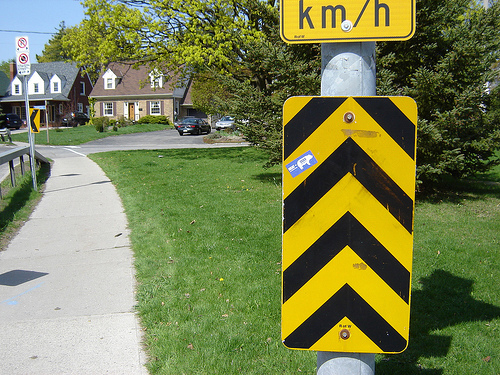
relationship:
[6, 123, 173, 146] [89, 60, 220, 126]
lawn in front of house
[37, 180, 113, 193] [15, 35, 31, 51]
shadow cast by sign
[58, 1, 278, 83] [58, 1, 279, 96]
flowers growing on tree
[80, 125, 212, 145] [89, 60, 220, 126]
driveway next to house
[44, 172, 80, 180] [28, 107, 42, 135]
shadow cast by sign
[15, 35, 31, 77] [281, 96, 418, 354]
sign to left of sign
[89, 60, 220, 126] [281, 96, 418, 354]
house behind sign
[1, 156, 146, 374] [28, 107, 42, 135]
sidewalk behind sign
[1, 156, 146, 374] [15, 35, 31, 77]
sidewalk behind sign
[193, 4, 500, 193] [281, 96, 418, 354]
evergreen behind sign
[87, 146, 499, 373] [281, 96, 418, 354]
grass behind sign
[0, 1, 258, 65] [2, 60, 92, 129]
sky above house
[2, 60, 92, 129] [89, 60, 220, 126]
house to left of house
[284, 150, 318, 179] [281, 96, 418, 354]
sticker attached to sign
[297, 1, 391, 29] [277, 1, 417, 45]
text printed on sign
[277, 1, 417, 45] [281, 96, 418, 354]
sign above sign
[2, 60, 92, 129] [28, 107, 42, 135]
house behind sign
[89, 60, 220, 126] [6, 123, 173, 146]
house behind lawn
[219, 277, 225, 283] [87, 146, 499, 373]
dandelion growing in grass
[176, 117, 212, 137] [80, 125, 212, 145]
car parked in driveway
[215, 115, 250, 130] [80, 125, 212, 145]
car parked in driveway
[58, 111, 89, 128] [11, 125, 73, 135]
car parked in driveway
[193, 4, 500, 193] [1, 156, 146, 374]
evergreen next to sidewalk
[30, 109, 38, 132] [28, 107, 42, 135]
arrow printed on sign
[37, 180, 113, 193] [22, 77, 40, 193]
shadow cast by sign post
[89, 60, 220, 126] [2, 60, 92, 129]
house next to house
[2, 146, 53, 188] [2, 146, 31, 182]
guard rail next to road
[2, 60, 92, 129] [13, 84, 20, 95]
house has window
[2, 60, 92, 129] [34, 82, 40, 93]
house has window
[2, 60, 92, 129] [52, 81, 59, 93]
house has window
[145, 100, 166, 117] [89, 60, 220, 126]
shutters attached to house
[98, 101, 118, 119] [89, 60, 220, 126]
shutters attached to house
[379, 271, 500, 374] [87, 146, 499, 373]
shadow on top of grass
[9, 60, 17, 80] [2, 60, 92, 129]
chimney on top of house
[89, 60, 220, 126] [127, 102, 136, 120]
house has front door